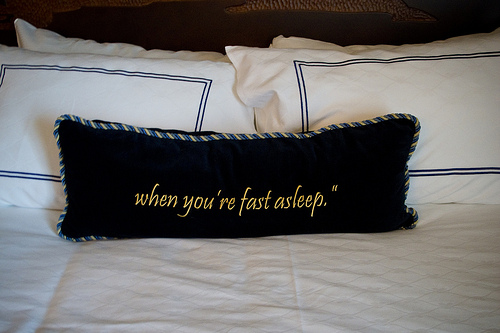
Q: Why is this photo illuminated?
A: Light fixtures.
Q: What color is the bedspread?
A: White.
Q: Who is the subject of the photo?
A: The pillows.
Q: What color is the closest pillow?
A: Black.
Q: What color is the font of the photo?
A: Yellow.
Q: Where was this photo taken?
A: In the bed.